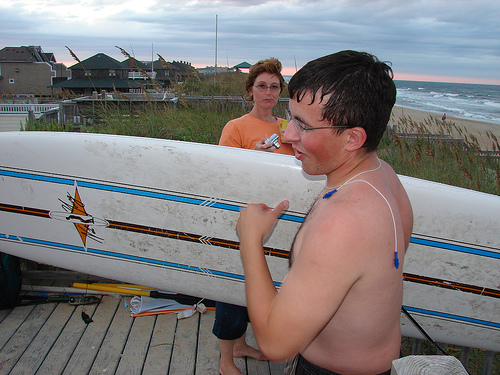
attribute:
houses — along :
[1, 42, 199, 114]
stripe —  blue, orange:
[2, 159, 498, 261]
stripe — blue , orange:
[0, 197, 498, 295]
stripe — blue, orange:
[4, 228, 496, 325]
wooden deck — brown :
[7, 295, 298, 372]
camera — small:
[231, 119, 325, 177]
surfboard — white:
[20, 132, 242, 287]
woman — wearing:
[220, 50, 313, 158]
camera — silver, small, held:
[264, 133, 282, 149]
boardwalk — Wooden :
[13, 310, 200, 372]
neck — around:
[326, 151, 377, 192]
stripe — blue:
[0, 168, 499, 264]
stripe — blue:
[2, 204, 499, 303]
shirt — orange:
[213, 112, 298, 153]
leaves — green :
[103, 87, 179, 125]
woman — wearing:
[209, 54, 299, 165]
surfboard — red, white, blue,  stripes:
[1, 125, 498, 355]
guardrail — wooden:
[29, 93, 54, 117]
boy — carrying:
[235, 43, 416, 373]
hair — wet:
[285, 47, 397, 155]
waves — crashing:
[395, 82, 498, 125]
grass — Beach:
[101, 105, 121, 136]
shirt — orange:
[231, 115, 291, 149]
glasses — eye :
[250, 78, 280, 95]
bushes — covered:
[92, 94, 207, 139]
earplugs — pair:
[337, 154, 398, 259]